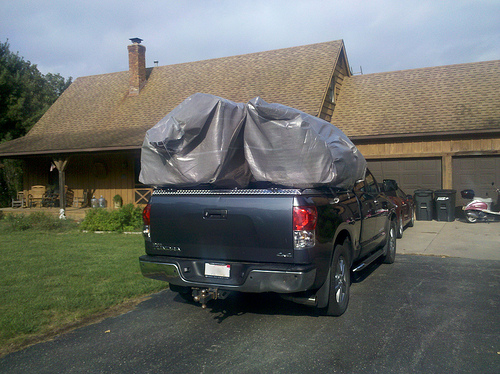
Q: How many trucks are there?
A: One.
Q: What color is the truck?
A: Navy.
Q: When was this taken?
A: During the day.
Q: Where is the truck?
A: In the driveway.